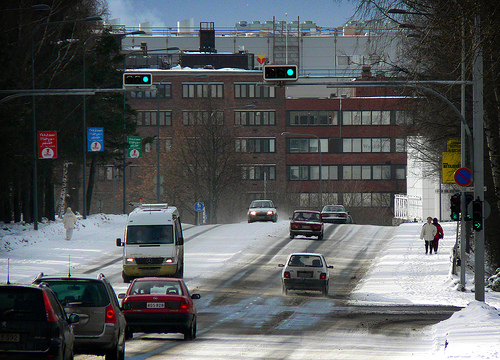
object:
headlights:
[127, 258, 132, 261]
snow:
[0, 213, 499, 359]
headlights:
[166, 258, 172, 262]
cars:
[289, 210, 324, 240]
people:
[420, 217, 437, 255]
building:
[91, 68, 429, 227]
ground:
[0, 222, 499, 360]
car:
[278, 252, 334, 293]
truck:
[117, 204, 184, 283]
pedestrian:
[62, 206, 77, 241]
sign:
[454, 168, 472, 187]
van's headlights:
[127, 259, 133, 262]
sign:
[39, 132, 57, 159]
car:
[117, 277, 200, 341]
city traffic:
[0, 199, 352, 360]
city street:
[0, 223, 499, 360]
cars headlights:
[322, 276, 325, 279]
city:
[0, 0, 499, 360]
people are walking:
[411, 212, 447, 248]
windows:
[189, 85, 195, 98]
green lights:
[143, 77, 148, 83]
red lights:
[285, 274, 288, 277]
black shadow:
[1, 213, 289, 253]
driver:
[290, 256, 304, 265]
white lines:
[393, 193, 398, 218]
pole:
[82, 33, 87, 217]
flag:
[256, 52, 265, 64]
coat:
[420, 223, 437, 241]